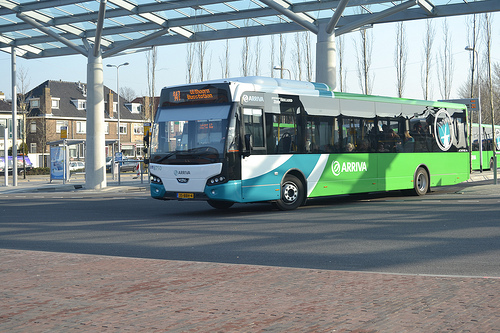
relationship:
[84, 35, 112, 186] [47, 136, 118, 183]
structure at bus stop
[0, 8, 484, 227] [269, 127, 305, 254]
shelter for people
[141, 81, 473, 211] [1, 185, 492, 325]
metro bus on street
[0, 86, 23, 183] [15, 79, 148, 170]
building beside house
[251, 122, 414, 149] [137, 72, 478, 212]
people riding on a bus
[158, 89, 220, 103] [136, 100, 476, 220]
digital letters and numbers on a bus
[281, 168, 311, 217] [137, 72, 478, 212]
wheel on bus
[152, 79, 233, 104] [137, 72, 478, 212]
sign on bus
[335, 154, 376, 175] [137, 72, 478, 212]
logo on bus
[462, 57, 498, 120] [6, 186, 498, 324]
tree on road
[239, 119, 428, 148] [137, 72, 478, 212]
people on bus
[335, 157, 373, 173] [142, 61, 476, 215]
arriba says on bus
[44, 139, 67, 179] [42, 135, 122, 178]
billboard on bus stop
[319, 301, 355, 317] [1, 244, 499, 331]
bricks on sidewalk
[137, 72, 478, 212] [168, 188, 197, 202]
bus has license plate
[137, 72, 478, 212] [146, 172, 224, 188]
bus has lights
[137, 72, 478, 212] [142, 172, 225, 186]
bus has headlights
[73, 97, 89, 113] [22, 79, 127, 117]
windows out of roof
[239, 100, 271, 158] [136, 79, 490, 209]
drivers window on bus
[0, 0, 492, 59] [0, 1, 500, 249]
roof of shelter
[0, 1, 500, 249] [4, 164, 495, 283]
shelter over road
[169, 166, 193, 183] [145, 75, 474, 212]
writing on front of bus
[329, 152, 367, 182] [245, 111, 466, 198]
company name printed on side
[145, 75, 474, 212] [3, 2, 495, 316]
bus parked at bus terminal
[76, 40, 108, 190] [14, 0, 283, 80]
cement pillars holding up covering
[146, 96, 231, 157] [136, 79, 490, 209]
window on front of bus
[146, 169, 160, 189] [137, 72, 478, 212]
headlights on front of bus